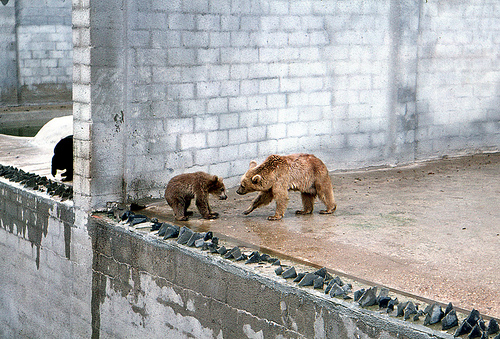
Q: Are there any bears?
A: Yes, there is a bear.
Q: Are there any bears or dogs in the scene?
A: Yes, there is a bear.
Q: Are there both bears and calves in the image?
A: No, there is a bear but no calves.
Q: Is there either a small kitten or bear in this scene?
A: Yes, there is a small bear.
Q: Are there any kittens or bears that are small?
A: Yes, the bear is small.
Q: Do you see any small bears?
A: Yes, there is a small bear.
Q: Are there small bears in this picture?
A: Yes, there is a small bear.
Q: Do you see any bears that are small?
A: Yes, there is a bear that is small.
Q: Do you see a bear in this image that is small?
A: Yes, there is a bear that is small.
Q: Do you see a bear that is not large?
A: Yes, there is a small bear.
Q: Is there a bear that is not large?
A: Yes, there is a small bear.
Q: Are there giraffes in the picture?
A: No, there are no giraffes.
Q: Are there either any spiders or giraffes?
A: No, there are no giraffes or spiders.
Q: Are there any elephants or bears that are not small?
A: No, there is a bear but it is small.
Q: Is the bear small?
A: Yes, the bear is small.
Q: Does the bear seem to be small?
A: Yes, the bear is small.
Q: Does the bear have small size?
A: Yes, the bear is small.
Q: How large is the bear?
A: The bear is small.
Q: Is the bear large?
A: No, the bear is small.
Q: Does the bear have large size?
A: No, the bear is small.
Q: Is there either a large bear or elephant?
A: No, there is a bear but it is small.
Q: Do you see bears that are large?
A: No, there is a bear but it is small.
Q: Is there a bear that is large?
A: No, there is a bear but it is small.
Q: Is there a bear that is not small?
A: No, there is a bear but it is small.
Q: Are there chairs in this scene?
A: No, there are no chairs.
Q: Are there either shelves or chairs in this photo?
A: No, there are no chairs or shelves.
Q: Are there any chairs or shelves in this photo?
A: No, there are no chairs or shelves.